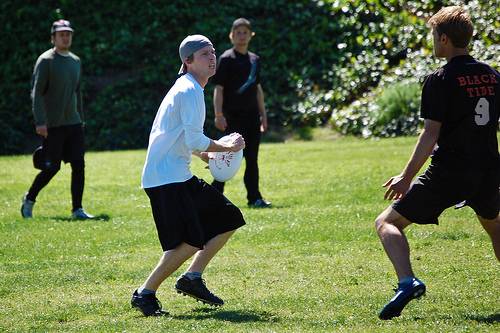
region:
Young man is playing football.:
[127, 30, 250, 321]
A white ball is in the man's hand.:
[207, 131, 247, 183]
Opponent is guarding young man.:
[366, 2, 497, 331]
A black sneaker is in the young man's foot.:
[171, 270, 226, 310]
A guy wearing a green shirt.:
[18, 17, 97, 227]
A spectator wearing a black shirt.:
[210, 17, 274, 209]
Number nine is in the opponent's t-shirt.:
[471, 95, 492, 129]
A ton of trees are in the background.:
[0, 0, 495, 135]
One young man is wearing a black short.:
[139, 175, 246, 251]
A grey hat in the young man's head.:
[176, 33, 214, 75]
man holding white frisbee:
[140, 26, 246, 312]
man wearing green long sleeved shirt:
[30, 20, 102, 227]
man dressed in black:
[372, 0, 497, 315]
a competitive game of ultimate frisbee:
[125, 5, 495, 315]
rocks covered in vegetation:
[8, 6, 355, 145]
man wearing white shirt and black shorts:
[132, 26, 240, 312]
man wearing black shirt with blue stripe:
[206, 16, 278, 211]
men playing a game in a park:
[22, 11, 497, 327]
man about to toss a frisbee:
[133, 16, 235, 322]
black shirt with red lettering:
[418, 61, 499, 168]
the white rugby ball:
[210, 127, 246, 180]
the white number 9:
[471, 100, 493, 135]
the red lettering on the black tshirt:
[450, 72, 499, 97]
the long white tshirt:
[140, 65, 215, 184]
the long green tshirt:
[18, 45, 102, 131]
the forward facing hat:
[45, 17, 82, 32]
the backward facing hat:
[162, 27, 212, 70]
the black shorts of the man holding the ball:
[132, 172, 248, 257]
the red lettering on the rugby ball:
[218, 152, 235, 165]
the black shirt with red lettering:
[419, 48, 497, 174]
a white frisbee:
[207, 128, 245, 187]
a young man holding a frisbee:
[135, 38, 232, 313]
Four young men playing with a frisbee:
[21, 38, 489, 320]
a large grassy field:
[260, 136, 380, 320]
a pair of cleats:
[118, 267, 227, 318]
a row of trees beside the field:
[45, 39, 415, 132]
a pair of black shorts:
[144, 168, 230, 251]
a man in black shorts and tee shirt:
[413, 38, 495, 323]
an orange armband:
[211, 108, 228, 122]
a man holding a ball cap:
[23, 41, 103, 229]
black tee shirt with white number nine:
[416, 63, 498, 142]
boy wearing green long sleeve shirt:
[20, 10, 107, 221]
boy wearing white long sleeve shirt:
[147, 25, 212, 164]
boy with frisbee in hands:
[155, 35, 254, 272]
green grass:
[300, 162, 360, 309]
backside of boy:
[408, 14, 498, 231]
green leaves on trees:
[273, 18, 382, 115]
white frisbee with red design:
[207, 123, 252, 185]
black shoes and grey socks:
[123, 253, 235, 318]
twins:
[33, 12, 289, 107]